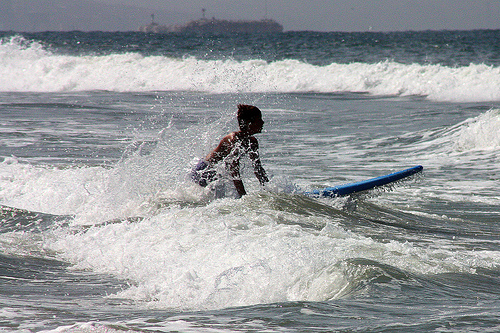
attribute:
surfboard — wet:
[291, 162, 425, 197]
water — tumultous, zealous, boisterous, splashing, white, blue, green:
[1, 30, 498, 331]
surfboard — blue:
[124, 155, 432, 215]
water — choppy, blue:
[216, 29, 397, 53]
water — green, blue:
[169, 39, 384, 119]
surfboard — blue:
[309, 158, 437, 225]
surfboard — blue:
[159, 158, 431, 211]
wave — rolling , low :
[116, 192, 333, 277]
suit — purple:
[190, 160, 218, 191]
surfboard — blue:
[286, 165, 426, 197]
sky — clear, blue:
[0, 1, 497, 33]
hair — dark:
[237, 103, 259, 124]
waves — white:
[1, 40, 495, 105]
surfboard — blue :
[311, 165, 423, 192]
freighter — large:
[139, 7, 283, 35]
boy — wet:
[172, 95, 286, 210]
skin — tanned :
[213, 153, 216, 154]